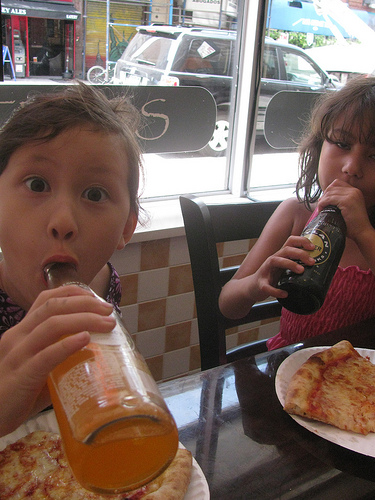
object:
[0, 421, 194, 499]
pizza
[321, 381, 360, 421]
melted cheese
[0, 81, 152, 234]
hair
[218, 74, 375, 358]
girl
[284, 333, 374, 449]
pizza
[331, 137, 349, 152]
eye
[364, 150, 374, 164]
eye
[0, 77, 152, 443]
child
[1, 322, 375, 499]
table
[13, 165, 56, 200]
eyes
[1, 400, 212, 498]
plate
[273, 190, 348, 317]
bottle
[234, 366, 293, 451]
shadow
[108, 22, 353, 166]
car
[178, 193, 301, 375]
black chair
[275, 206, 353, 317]
beer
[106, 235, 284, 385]
checkered wall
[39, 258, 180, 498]
bottle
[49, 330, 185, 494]
soda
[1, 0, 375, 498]
pizza shop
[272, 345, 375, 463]
paper plate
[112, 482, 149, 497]
sauce